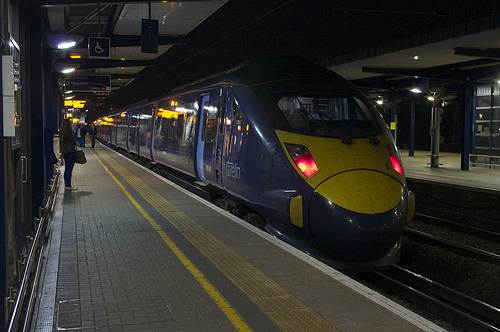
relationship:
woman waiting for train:
[60, 115, 90, 191] [91, 64, 414, 263]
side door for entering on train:
[193, 97, 215, 190] [91, 64, 414, 263]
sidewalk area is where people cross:
[77, 140, 181, 206] [80, 117, 122, 168]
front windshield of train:
[279, 95, 377, 140] [91, 64, 414, 263]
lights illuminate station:
[54, 38, 80, 86] [6, 4, 500, 331]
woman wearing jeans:
[60, 115, 90, 191] [61, 155, 79, 188]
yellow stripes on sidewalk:
[99, 156, 161, 220] [79, 134, 222, 220]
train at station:
[91, 64, 414, 263] [6, 4, 500, 331]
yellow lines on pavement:
[101, 157, 246, 282] [86, 208, 163, 290]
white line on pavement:
[110, 147, 236, 218] [86, 208, 163, 290]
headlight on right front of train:
[290, 145, 324, 179] [91, 64, 414, 263]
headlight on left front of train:
[382, 150, 404, 179] [91, 64, 414, 263]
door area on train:
[193, 97, 215, 190] [91, 64, 414, 263]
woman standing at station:
[60, 115, 90, 191] [6, 4, 500, 331]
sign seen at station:
[143, 8, 163, 65] [6, 4, 500, 331]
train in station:
[91, 64, 414, 263] [6, 4, 500, 331]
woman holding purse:
[60, 115, 90, 191] [75, 148, 89, 165]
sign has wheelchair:
[91, 37, 116, 62] [93, 43, 103, 57]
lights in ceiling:
[54, 38, 80, 86] [45, 3, 222, 106]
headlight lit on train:
[290, 145, 324, 179] [91, 64, 414, 263]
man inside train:
[183, 118, 199, 145] [91, 64, 414, 263]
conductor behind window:
[183, 118, 199, 145] [182, 107, 199, 147]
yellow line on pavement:
[99, 156, 161, 220] [86, 208, 163, 290]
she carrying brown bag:
[60, 115, 90, 191] [75, 148, 89, 165]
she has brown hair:
[60, 115, 90, 191] [62, 114, 76, 134]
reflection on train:
[116, 114, 183, 165] [91, 64, 414, 263]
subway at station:
[91, 64, 414, 263] [6, 4, 500, 331]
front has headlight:
[277, 129, 413, 213] [290, 145, 324, 179]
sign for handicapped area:
[91, 37, 116, 62] [65, 26, 121, 86]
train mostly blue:
[91, 64, 414, 263] [91, 68, 276, 214]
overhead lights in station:
[47, 42, 91, 120] [6, 4, 500, 331]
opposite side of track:
[331, 35, 500, 165] [360, 207, 498, 313]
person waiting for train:
[60, 115, 90, 191] [91, 64, 414, 263]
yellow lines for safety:
[101, 157, 246, 282] [109, 158, 217, 237]